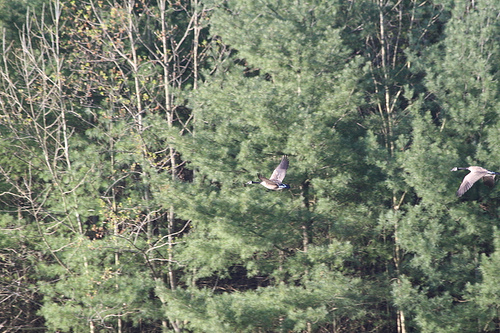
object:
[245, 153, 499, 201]
birds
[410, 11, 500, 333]
tree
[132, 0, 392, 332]
tree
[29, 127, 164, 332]
tree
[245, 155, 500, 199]
ducks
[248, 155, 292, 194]
duck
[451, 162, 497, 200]
duck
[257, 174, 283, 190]
wings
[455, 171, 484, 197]
wings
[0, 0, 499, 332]
trees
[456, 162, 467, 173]
neck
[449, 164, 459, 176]
face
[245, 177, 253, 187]
face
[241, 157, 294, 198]
goose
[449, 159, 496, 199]
goose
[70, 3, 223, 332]
forest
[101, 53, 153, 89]
leaves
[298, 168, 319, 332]
truck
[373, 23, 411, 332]
tree trunk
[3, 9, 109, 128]
branches